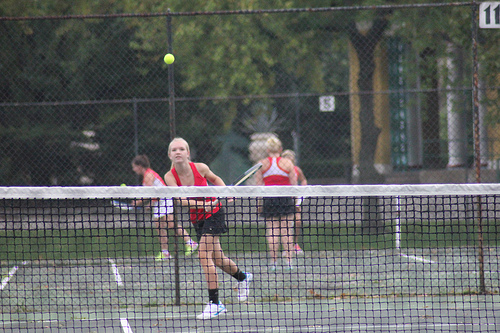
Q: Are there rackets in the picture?
A: Yes, there is a racket.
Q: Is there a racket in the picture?
A: Yes, there is a racket.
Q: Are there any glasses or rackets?
A: Yes, there is a racket.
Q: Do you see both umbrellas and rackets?
A: No, there is a racket but no umbrellas.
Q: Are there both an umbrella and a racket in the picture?
A: No, there is a racket but no umbrellas.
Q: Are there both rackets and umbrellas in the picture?
A: No, there is a racket but no umbrellas.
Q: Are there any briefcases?
A: No, there are no briefcases.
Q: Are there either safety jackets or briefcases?
A: No, there are no briefcases or safety jackets.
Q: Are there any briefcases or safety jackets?
A: No, there are no briefcases or safety jackets.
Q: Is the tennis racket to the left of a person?
A: No, the tennis racket is to the right of a person.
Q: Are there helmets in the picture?
A: No, there are no helmets.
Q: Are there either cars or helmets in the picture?
A: No, there are no helmets or cars.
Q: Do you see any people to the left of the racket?
A: Yes, there is a person to the left of the racket.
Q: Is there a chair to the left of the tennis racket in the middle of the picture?
A: No, there is a person to the left of the tennis racket.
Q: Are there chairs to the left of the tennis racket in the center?
A: No, there is a person to the left of the tennis racket.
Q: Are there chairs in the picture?
A: No, there are no chairs.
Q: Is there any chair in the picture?
A: No, there are no chairs.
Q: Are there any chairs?
A: No, there are no chairs.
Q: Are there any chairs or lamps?
A: No, there are no chairs or lamps.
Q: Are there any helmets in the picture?
A: No, there are no helmets.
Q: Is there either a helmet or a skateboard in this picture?
A: No, there are no helmets or skateboards.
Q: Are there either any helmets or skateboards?
A: No, there are no helmets or skateboards.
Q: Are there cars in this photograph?
A: No, there are no cars.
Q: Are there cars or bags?
A: No, there are no cars or bags.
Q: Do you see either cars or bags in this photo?
A: No, there are no cars or bags.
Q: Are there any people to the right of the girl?
A: Yes, there is a person to the right of the girl.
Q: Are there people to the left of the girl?
A: No, the person is to the right of the girl.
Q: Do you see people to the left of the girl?
A: No, the person is to the right of the girl.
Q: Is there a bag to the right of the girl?
A: No, there is a person to the right of the girl.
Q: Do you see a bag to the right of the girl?
A: No, there is a person to the right of the girl.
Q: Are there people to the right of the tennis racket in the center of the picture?
A: Yes, there is a person to the right of the racket.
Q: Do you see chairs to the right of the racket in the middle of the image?
A: No, there is a person to the right of the tennis racket.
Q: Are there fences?
A: Yes, there is a fence.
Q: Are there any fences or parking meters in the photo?
A: Yes, there is a fence.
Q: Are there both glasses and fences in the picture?
A: No, there is a fence but no glasses.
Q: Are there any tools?
A: No, there are no tools.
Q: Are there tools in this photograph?
A: No, there are no tools.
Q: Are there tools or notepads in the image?
A: No, there are no tools or notepads.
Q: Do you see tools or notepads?
A: No, there are no tools or notepads.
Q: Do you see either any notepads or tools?
A: No, there are no tools or notepads.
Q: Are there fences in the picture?
A: Yes, there is a fence.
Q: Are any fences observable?
A: Yes, there is a fence.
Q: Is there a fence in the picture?
A: Yes, there is a fence.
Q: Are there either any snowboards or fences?
A: Yes, there is a fence.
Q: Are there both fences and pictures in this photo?
A: No, there is a fence but no pictures.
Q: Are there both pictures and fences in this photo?
A: No, there is a fence but no pictures.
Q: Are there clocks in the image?
A: No, there are no clocks.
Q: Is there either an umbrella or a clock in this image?
A: No, there are no clocks or umbrellas.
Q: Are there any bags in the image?
A: No, there are no bags.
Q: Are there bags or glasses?
A: No, there are no bags or glasses.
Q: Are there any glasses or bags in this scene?
A: No, there are no bags or glasses.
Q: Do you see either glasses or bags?
A: No, there are no bags or glasses.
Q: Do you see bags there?
A: No, there are no bags.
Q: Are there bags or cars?
A: No, there are no bags or cars.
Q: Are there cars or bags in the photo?
A: No, there are no bags or cars.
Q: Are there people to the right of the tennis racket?
A: Yes, there are people to the right of the tennis racket.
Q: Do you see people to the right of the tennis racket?
A: Yes, there are people to the right of the tennis racket.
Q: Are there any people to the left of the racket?
A: No, the people are to the right of the racket.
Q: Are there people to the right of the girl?
A: Yes, there are people to the right of the girl.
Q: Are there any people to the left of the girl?
A: No, the people are to the right of the girl.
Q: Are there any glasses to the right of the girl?
A: No, there are people to the right of the girl.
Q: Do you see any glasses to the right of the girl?
A: No, there are people to the right of the girl.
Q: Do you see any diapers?
A: No, there are no diapers.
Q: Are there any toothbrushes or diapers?
A: No, there are no diapers or toothbrushes.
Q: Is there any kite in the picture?
A: No, there are no kites.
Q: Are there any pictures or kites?
A: No, there are no kites or pictures.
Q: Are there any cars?
A: No, there are no cars.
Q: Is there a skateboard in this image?
A: No, there are no skateboards.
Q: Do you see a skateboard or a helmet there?
A: No, there are no skateboards or helmets.